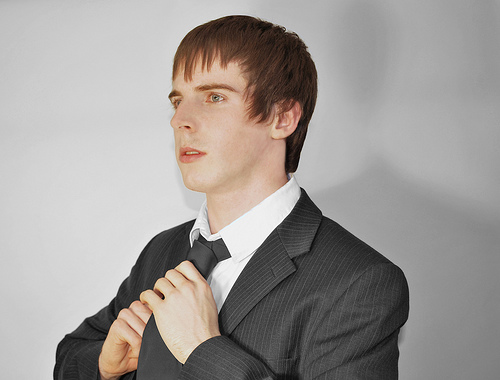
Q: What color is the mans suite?
A: Black.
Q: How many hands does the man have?
A: Two.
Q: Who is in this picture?
A: A man.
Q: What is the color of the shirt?
A: White.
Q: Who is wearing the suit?
A: The man.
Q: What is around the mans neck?
A: A tie.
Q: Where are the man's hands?
A: On his tie.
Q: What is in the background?
A: A wall.